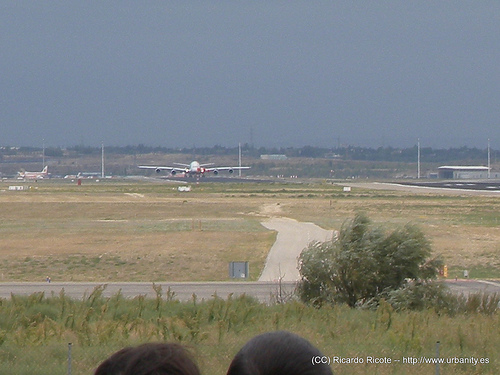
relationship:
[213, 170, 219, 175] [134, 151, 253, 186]
engine of plane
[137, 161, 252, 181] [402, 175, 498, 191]
aircraft on runway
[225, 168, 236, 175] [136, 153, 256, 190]
engine on plane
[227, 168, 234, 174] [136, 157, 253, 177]
engine on plane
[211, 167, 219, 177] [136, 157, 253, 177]
engine on plane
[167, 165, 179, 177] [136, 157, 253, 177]
engine on plane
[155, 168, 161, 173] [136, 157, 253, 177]
engine on plane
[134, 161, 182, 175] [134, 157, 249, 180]
wing of plane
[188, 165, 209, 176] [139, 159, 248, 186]
lights on plane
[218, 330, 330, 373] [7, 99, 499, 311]
person watching airport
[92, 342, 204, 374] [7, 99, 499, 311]
person watching airport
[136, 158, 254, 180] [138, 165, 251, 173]
aircraft has wings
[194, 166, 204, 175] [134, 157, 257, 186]
tail of airplane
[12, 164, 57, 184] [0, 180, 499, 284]
aircraft on dry grass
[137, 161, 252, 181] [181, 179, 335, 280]
aircraft on runway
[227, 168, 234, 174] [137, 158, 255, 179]
engine on airplane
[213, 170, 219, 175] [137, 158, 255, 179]
engine on airplane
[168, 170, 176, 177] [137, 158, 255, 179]
engine on airplane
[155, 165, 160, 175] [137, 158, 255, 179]
engine on airplane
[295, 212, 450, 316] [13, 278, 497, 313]
tree near runway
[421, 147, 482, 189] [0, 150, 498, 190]
hangar at airport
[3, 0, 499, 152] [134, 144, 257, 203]
sky above airplane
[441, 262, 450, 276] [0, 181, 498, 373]
pole near grass